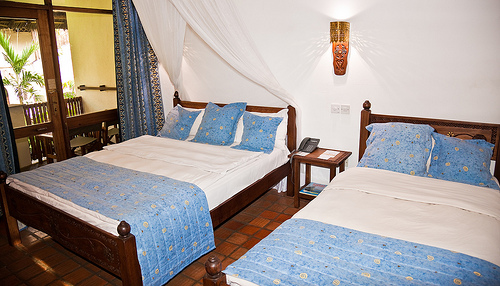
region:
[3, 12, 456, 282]
two beds in a room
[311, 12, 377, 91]
wall light sconce with tropical theme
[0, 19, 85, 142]
small palm tree outside the room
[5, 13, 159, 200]
outdoor patio visible through the glass window and door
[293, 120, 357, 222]
telephone on the nightstand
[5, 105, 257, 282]
tile flooring in the room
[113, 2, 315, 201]
mosquito net over one of the beds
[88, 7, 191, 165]
tropical decoration on curtains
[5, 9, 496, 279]
a hotel room in a tropical location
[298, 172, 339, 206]
magazine on the lower shelf of the nightstand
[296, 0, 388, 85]
the light is on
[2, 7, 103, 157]
a door shows outside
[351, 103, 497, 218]
two pillows on bed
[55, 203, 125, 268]
bed made of wood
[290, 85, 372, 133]
light switches on wall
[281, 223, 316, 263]
blue and yellow bedspread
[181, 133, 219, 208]
white sheets on bed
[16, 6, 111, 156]
door made of wood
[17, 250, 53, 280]
tile is on floor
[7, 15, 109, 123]
a door to outside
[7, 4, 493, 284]
two queen beds in a hotel room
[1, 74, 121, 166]
balcony outside a bedroom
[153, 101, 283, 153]
three decorative pillows on a bed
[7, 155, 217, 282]
a blue coverlet on a queen size bed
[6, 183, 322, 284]
terracotta tiling on the floor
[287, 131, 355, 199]
telephone on a small side table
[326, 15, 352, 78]
a decorative wall light is switched on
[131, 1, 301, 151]
white drapes hang from the ceiling to the headboard of a bed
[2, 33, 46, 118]
palm tree outside the bedroom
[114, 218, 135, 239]
wooden knob on the top of a bedpost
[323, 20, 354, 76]
wall light between the beds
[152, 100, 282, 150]
blue and white pillows on bed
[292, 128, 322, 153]
phone on table between beds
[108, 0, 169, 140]
blue patterned window curtain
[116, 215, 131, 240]
one of the bed post knobs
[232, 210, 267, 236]
brown floor tiles in bedroom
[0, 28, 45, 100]
palm tree outside by balcony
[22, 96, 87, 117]
balcony railing outside of room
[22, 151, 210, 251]
blue patterned cover at foot of bed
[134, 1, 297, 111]
white bed canopy at head of bed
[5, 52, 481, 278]
Two beds in the room.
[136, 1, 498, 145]
A large white sheet behind the beds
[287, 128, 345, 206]
A small table between the two beds.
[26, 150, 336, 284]
Brown tiles on the floor.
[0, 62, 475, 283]
Brown wooden bed frames.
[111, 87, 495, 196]
Matching pillows across the beds.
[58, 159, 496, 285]
Matching blankets across the beds.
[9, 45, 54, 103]
A palm tree outside.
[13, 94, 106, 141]
Railings for protection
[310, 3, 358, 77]
A light fixture between the beds.